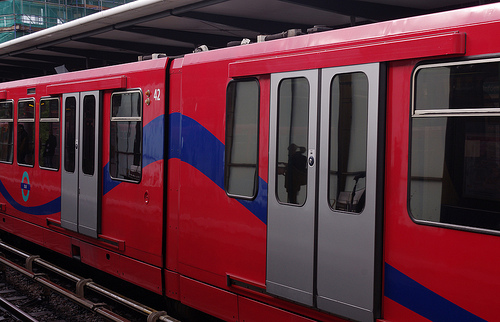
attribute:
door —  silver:
[256, 74, 394, 298]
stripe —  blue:
[126, 93, 476, 320]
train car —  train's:
[3, 61, 497, 308]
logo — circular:
[16, 168, 38, 198]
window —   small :
[324, 72, 373, 217]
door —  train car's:
[313, 59, 382, 316]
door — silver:
[59, 92, 100, 239]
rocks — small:
[11, 262, 51, 319]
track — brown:
[13, 229, 111, 319]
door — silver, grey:
[264, 68, 386, 317]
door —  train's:
[276, 69, 388, 319]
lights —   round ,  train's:
[142, 83, 154, 113]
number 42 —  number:
[149, 85, 161, 102]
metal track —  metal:
[1, 298, 41, 320]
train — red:
[5, 46, 317, 312]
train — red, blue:
[6, 18, 481, 245]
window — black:
[400, 59, 498, 232]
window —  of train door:
[319, 66, 389, 230]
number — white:
[148, 88, 163, 100]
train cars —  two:
[3, 7, 496, 319]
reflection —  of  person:
[282, 142, 306, 202]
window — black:
[407, 52, 499, 236]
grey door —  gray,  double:
[263, 58, 390, 320]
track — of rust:
[2, 292, 31, 319]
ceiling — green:
[5, 5, 364, 72]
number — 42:
[150, 86, 161, 101]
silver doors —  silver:
[267, 61, 388, 320]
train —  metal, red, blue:
[1, 0, 498, 320]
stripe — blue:
[6, 113, 482, 320]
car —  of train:
[0, 59, 166, 296]